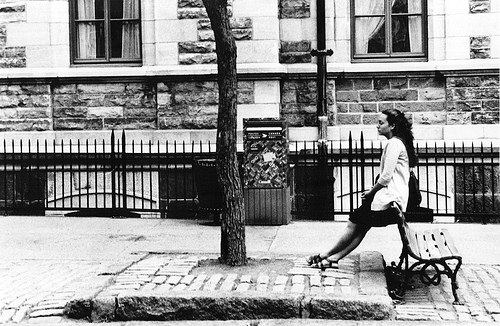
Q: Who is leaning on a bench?
A: A woman in sandals.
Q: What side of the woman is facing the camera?
A: Her left.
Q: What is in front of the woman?
A: A tree trunk.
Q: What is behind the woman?
A: A bench.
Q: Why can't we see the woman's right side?
A: She is facing left.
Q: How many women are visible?
A: One.